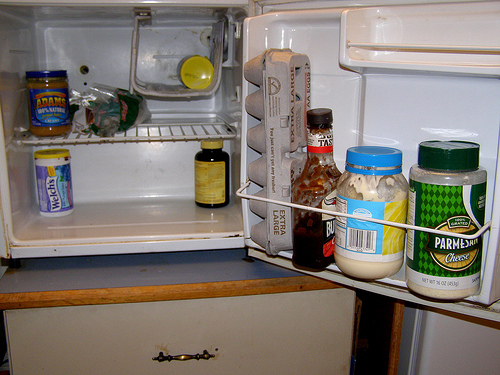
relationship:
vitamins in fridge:
[197, 138, 230, 209] [1, 2, 498, 304]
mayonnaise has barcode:
[337, 147, 407, 280] [348, 228, 377, 253]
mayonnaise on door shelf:
[337, 147, 407, 280] [238, 171, 487, 302]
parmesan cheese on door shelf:
[407, 141, 487, 301] [238, 171, 487, 302]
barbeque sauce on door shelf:
[291, 108, 336, 268] [238, 171, 487, 302]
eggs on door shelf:
[242, 50, 309, 258] [238, 171, 487, 302]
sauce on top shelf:
[26, 70, 71, 136] [21, 115, 242, 145]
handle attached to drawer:
[154, 348, 212, 363] [4, 288, 354, 375]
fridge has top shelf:
[1, 2, 498, 304] [21, 115, 242, 145]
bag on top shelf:
[80, 85, 154, 137] [21, 115, 242, 145]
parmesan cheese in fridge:
[407, 141, 487, 301] [1, 2, 498, 304]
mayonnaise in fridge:
[337, 147, 407, 280] [1, 2, 498, 304]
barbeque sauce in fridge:
[291, 108, 336, 268] [1, 2, 498, 304]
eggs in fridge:
[242, 50, 309, 258] [1, 2, 498, 304]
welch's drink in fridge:
[33, 149, 73, 216] [1, 2, 498, 304]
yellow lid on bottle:
[198, 138, 225, 150] [196, 149, 230, 208]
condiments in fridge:
[291, 110, 479, 300] [1, 2, 498, 304]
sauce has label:
[26, 70, 71, 136] [29, 85, 67, 124]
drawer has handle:
[4, 288, 354, 375] [154, 348, 212, 363]